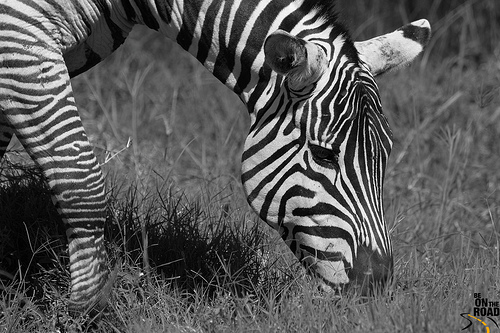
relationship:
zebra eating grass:
[0, 0, 428, 333] [4, 27, 484, 327]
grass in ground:
[0, 10, 500, 333] [13, 15, 480, 324]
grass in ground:
[96, 40, 194, 89] [13, 15, 480, 324]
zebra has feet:
[0, 0, 428, 333] [73, 284, 108, 330]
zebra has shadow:
[0, 0, 428, 333] [133, 203, 270, 293]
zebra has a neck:
[0, 0, 428, 333] [214, 20, 262, 95]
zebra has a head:
[0, 0, 428, 333] [261, 83, 397, 290]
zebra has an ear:
[0, 0, 428, 333] [263, 26, 328, 93]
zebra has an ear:
[0, 0, 428, 333] [368, 19, 438, 75]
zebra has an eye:
[0, 0, 428, 333] [305, 132, 338, 173]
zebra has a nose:
[0, 0, 428, 333] [343, 244, 387, 287]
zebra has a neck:
[0, 0, 428, 333] [206, 26, 266, 92]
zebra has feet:
[0, 0, 428, 333] [52, 254, 112, 312]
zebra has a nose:
[0, 0, 428, 333] [351, 246, 395, 297]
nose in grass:
[351, 246, 395, 297] [391, 280, 442, 322]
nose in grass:
[351, 246, 395, 297] [283, 285, 335, 325]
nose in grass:
[351, 246, 395, 297] [353, 294, 408, 327]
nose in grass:
[351, 246, 395, 297] [423, 253, 464, 295]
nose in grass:
[351, 246, 395, 297] [338, 292, 408, 322]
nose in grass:
[351, 246, 395, 297] [345, 295, 415, 328]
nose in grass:
[351, 246, 395, 297] [372, 295, 418, 325]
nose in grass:
[355, 253, 396, 302] [354, 302, 417, 331]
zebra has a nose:
[237, 27, 425, 297] [355, 253, 396, 302]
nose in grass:
[351, 246, 395, 297] [344, 293, 405, 321]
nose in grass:
[351, 246, 395, 297] [355, 298, 420, 328]